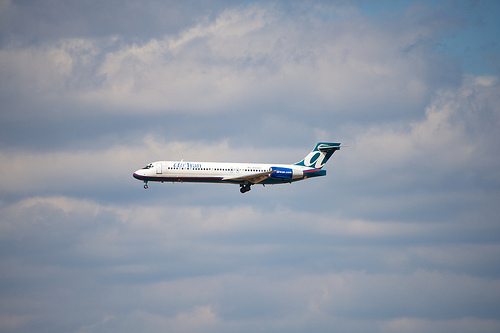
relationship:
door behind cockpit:
[155, 162, 165, 178] [132, 156, 155, 185]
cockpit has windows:
[133, 156, 160, 186] [141, 158, 157, 170]